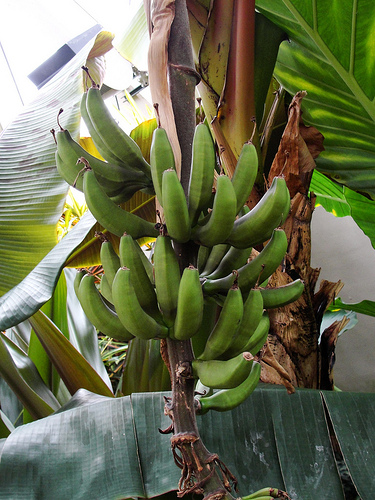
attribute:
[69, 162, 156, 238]
banana — green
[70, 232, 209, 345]
bananas — green, bundle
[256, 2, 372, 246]
leaf — green, broad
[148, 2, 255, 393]
stick — brown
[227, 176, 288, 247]
banana — Green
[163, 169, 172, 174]
nub — brown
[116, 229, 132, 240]
nub — brown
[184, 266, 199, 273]
nub — brown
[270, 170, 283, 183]
nub — brown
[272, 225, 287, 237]
nub — brown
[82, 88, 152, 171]
bananas — Green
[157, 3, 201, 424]
stick — brown 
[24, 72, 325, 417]
banana — green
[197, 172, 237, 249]
banana — green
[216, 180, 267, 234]
banana — small, green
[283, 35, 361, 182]
banana leaf — large green banana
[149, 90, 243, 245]
banana — green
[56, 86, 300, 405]
bananas — Green 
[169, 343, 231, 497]
stick — brown  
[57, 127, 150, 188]
banana — green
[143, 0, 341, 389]
trunk — complicated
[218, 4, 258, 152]
stick — brown 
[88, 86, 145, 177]
banana — Green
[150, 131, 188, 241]
bananas — Unripe green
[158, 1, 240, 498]
brown stick — brown  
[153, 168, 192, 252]
banana — green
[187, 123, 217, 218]
banana — green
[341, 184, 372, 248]
leaf — dark green, textured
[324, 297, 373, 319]
leaf — dark green, textured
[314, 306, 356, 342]
leaf — dark green, textured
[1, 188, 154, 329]
leaf — dark green, textured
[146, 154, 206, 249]
banana — green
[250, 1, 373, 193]
leaf — large green , dark green, textured, broad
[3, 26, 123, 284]
leaf — broad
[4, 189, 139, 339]
leaf — broad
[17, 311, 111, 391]
leaf — broad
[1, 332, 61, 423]
leaf — broad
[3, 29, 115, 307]
leaf — large yellow green banana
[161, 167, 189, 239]
banana — Green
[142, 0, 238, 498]
stick — brown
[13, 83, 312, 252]
bananas — green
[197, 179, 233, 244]
bananas — large group, small green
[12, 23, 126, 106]
purple box — square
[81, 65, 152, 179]
banana — green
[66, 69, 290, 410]
bananas — Green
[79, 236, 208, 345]
banana — green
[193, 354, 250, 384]
banana — green 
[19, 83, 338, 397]
green bananas — green ,  upwards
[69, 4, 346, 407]
tree — banana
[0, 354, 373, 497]
trunk — large brown banana tree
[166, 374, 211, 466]
stick — brown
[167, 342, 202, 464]
stem — brown